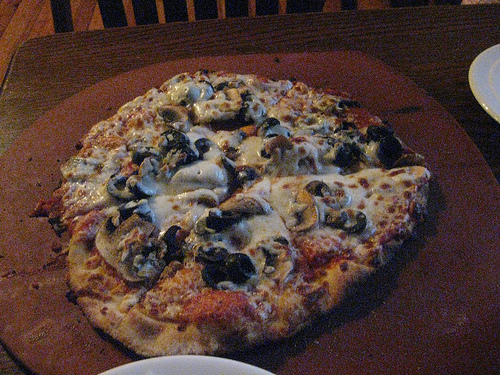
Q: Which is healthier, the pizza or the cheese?
A: The cheese is healthier than the pizza.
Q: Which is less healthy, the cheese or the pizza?
A: The pizza is less healthy than the cheese.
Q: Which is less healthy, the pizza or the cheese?
A: The pizza is less healthy than the cheese.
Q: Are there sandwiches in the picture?
A: No, there are no sandwiches.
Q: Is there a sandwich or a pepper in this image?
A: No, there are no sandwiches or peppers.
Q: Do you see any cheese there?
A: Yes, there is cheese.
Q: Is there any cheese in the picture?
A: Yes, there is cheese.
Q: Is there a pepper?
A: No, there are no peppers.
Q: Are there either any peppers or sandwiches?
A: No, there are no peppers or sandwiches.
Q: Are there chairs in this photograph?
A: Yes, there is a chair.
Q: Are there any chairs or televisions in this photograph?
A: Yes, there is a chair.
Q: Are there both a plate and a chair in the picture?
A: Yes, there are both a chair and a plate.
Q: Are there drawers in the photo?
A: No, there are no drawers.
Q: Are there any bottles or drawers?
A: No, there are no drawers or bottles.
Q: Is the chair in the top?
A: Yes, the chair is in the top of the image.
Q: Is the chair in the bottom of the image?
A: No, the chair is in the top of the image.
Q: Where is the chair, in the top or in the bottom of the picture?
A: The chair is in the top of the image.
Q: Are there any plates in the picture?
A: Yes, there is a plate.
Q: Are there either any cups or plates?
A: Yes, there is a plate.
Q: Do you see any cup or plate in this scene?
A: Yes, there is a plate.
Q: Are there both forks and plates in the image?
A: No, there is a plate but no forks.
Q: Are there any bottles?
A: No, there are no bottles.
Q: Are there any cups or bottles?
A: No, there are no bottles or cups.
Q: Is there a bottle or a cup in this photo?
A: No, there are no bottles or cups.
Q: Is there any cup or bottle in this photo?
A: No, there are no bottles or cups.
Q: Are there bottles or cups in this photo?
A: No, there are no bottles or cups.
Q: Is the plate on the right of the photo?
A: Yes, the plate is on the right of the image.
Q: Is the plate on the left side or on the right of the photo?
A: The plate is on the right of the image.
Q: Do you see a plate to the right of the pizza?
A: Yes, there is a plate to the right of the pizza.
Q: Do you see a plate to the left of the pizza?
A: No, the plate is to the right of the pizza.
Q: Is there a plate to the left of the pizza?
A: No, the plate is to the right of the pizza.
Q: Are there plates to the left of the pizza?
A: No, the plate is to the right of the pizza.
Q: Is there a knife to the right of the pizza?
A: No, there is a plate to the right of the pizza.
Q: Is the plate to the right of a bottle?
A: No, the plate is to the right of the pizza.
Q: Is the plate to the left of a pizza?
A: No, the plate is to the right of a pizza.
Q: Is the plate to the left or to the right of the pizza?
A: The plate is to the right of the pizza.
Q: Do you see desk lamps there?
A: No, there are no desk lamps.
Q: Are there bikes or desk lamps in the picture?
A: No, there are no desk lamps or bikes.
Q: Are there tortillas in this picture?
A: No, there are no tortillas.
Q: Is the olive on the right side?
A: Yes, the olive is on the right of the image.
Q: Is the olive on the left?
A: No, the olive is on the right of the image.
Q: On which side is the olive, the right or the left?
A: The olive is on the right of the image.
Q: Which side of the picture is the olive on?
A: The olive is on the right of the image.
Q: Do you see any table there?
A: Yes, there is a table.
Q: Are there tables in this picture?
A: Yes, there is a table.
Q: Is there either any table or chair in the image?
A: Yes, there is a table.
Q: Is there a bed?
A: No, there are no beds.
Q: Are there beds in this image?
A: No, there are no beds.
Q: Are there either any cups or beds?
A: No, there are no beds or cups.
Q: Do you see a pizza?
A: Yes, there is a pizza.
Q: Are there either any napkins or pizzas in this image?
A: Yes, there is a pizza.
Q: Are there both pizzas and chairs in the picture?
A: Yes, there are both a pizza and a chair.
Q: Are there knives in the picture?
A: No, there are no knives.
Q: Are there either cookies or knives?
A: No, there are no knives or cookies.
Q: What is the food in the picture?
A: The food is a pizza.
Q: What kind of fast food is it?
A: The food is a pizza.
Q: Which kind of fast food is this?
A: This is a pizza.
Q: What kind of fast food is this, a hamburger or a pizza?
A: This is a pizza.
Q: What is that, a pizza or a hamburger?
A: That is a pizza.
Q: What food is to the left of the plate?
A: The food is a pizza.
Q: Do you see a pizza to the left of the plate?
A: Yes, there is a pizza to the left of the plate.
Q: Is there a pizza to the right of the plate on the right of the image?
A: No, the pizza is to the left of the plate.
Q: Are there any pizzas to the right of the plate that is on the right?
A: No, the pizza is to the left of the plate.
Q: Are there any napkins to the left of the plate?
A: No, there is a pizza to the left of the plate.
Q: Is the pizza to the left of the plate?
A: Yes, the pizza is to the left of the plate.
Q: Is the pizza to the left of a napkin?
A: No, the pizza is to the left of the plate.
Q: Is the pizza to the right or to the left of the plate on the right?
A: The pizza is to the left of the plate.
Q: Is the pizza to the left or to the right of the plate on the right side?
A: The pizza is to the left of the plate.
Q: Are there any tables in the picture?
A: Yes, there is a table.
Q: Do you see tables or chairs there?
A: Yes, there is a table.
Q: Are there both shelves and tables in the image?
A: No, there is a table but no shelves.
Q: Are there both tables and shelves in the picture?
A: No, there is a table but no shelves.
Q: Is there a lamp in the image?
A: No, there are no lamps.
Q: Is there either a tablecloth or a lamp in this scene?
A: No, there are no lamps or tablecloths.